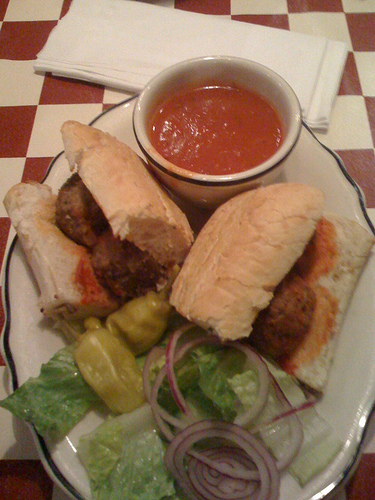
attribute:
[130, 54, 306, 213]
cup — small 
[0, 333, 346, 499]
lettuce — green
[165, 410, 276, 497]
onions — red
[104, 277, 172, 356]
pepper — Green 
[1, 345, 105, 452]
lettuce — green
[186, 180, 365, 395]
sandwich — meatball, sub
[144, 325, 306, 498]
onion — red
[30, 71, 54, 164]
tablecloth — red, white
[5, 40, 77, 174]
mat — checkered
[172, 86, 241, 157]
sauce — italian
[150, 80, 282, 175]
sauce — red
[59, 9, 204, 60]
white napkins — stacked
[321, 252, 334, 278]
sauce — red 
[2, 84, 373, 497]
plate — white, black, trim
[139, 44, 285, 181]
bowl — round, white, dipping, black, trim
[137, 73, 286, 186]
sauce — red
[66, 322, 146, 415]
pepper — green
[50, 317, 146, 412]
pepper — pepperoncini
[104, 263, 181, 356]
pepper — pepperoncini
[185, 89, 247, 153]
sauce — tomato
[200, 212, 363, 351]
sandwich — sub, meatball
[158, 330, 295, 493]
onion — purple, slices